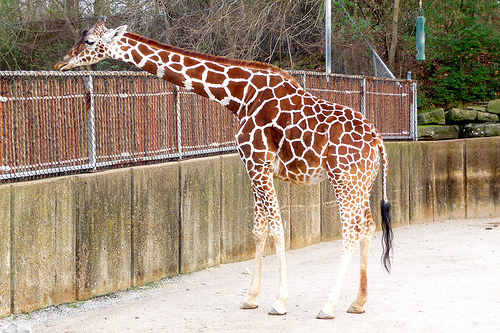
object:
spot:
[57, 17, 389, 254]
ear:
[102, 25, 127, 45]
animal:
[54, 16, 393, 319]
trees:
[0, 0, 499, 140]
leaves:
[432, 45, 500, 103]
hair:
[123, 31, 295, 82]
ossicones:
[97, 14, 107, 26]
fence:
[0, 70, 419, 180]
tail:
[379, 144, 395, 275]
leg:
[240, 199, 267, 309]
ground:
[0, 217, 499, 332]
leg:
[316, 159, 365, 320]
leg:
[345, 187, 375, 314]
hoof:
[240, 296, 287, 315]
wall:
[0, 138, 499, 319]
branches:
[0, 0, 392, 71]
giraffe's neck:
[121, 35, 244, 110]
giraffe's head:
[54, 16, 128, 71]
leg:
[250, 158, 289, 315]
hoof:
[316, 302, 366, 319]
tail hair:
[380, 199, 394, 276]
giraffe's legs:
[240, 164, 376, 319]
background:
[0, 1, 499, 142]